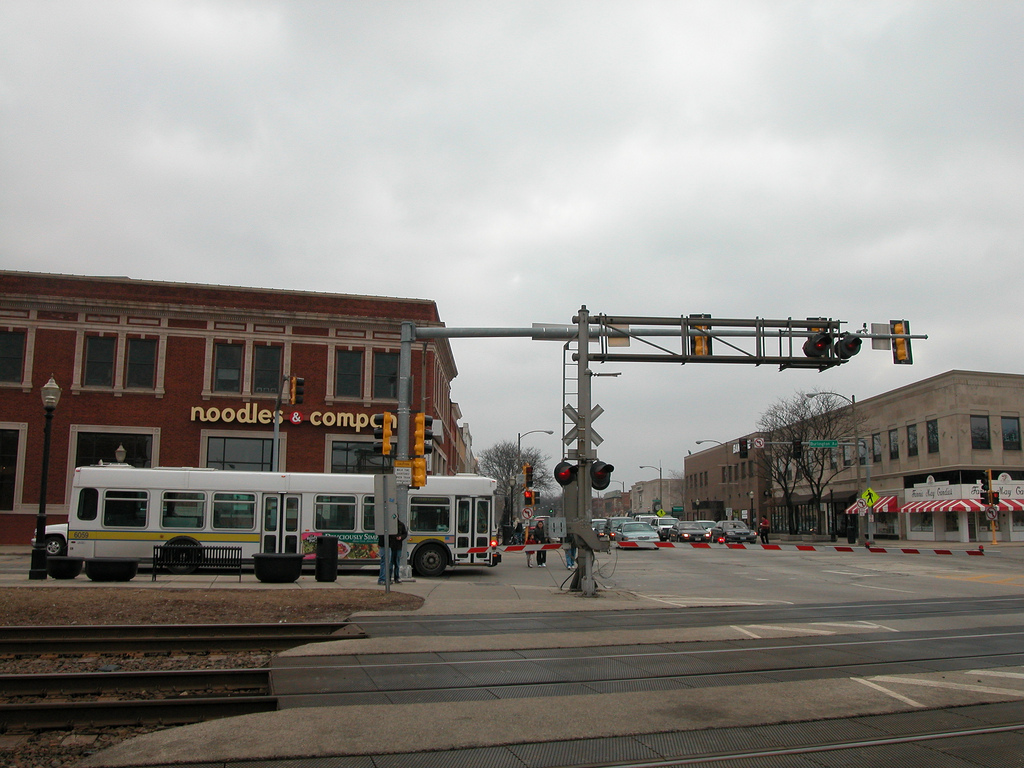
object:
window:
[242, 309, 303, 404]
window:
[361, 336, 409, 419]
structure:
[525, 297, 949, 658]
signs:
[586, 304, 646, 359]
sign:
[551, 396, 635, 451]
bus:
[24, 423, 549, 601]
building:
[0, 208, 1024, 604]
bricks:
[170, 354, 178, 360]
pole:
[553, 331, 625, 604]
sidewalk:
[0, 527, 447, 627]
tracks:
[0, 686, 269, 722]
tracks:
[0, 655, 273, 692]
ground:
[0, 544, 1023, 768]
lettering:
[184, 397, 208, 433]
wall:
[0, 255, 436, 569]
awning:
[837, 477, 906, 524]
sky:
[3, 4, 1022, 493]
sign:
[187, 395, 407, 435]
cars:
[611, 507, 669, 558]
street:
[0, 522, 1021, 764]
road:
[289, 534, 1023, 766]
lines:
[845, 669, 930, 709]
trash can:
[295, 519, 356, 602]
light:
[36, 368, 71, 417]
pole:
[21, 402, 60, 591]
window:
[210, 336, 245, 395]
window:
[328, 339, 371, 418]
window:
[114, 318, 163, 403]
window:
[202, 430, 286, 478]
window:
[325, 431, 394, 480]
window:
[0, 318, 35, 392]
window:
[966, 411, 993, 455]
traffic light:
[411, 411, 425, 458]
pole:
[383, 304, 423, 582]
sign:
[520, 502, 534, 523]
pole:
[518, 462, 538, 546]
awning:
[894, 476, 987, 519]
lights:
[551, 458, 576, 491]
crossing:
[599, 539, 1023, 608]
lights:
[802, 331, 840, 361]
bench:
[143, 538, 245, 584]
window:
[72, 328, 127, 396]